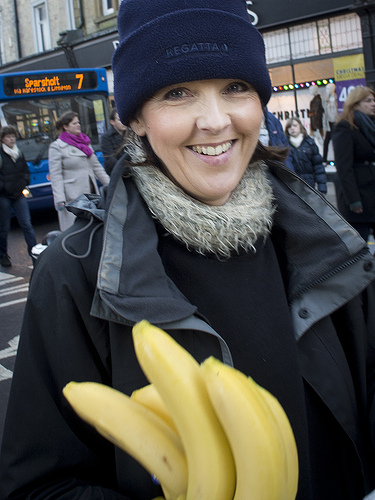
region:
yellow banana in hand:
[203, 361, 283, 497]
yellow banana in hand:
[75, 393, 178, 486]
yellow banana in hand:
[141, 329, 203, 497]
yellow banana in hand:
[132, 388, 156, 413]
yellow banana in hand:
[240, 386, 295, 452]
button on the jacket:
[291, 308, 313, 324]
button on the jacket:
[360, 261, 373, 274]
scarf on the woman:
[180, 213, 250, 248]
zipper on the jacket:
[323, 271, 347, 279]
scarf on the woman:
[70, 134, 92, 157]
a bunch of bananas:
[60, 319, 303, 499]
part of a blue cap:
[83, 0, 282, 124]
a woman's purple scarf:
[56, 128, 94, 159]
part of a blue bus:
[0, 66, 108, 204]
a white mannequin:
[301, 85, 327, 154]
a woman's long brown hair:
[338, 85, 373, 125]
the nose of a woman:
[193, 90, 232, 137]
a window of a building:
[32, 6, 49, 52]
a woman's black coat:
[286, 137, 329, 192]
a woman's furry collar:
[125, 145, 273, 252]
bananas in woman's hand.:
[186, 424, 224, 471]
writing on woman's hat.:
[167, 42, 236, 54]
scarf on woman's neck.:
[70, 137, 95, 154]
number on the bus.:
[73, 71, 89, 92]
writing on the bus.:
[11, 74, 71, 98]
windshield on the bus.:
[24, 111, 48, 130]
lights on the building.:
[280, 81, 306, 94]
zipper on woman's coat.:
[303, 247, 359, 294]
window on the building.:
[39, 6, 45, 53]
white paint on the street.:
[7, 277, 23, 293]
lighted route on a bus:
[4, 58, 114, 99]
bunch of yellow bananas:
[45, 309, 346, 497]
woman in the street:
[13, 3, 363, 498]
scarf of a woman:
[131, 171, 297, 260]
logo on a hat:
[161, 35, 234, 65]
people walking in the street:
[0, 118, 118, 276]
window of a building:
[27, 2, 56, 61]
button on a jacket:
[289, 305, 317, 322]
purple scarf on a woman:
[60, 131, 100, 161]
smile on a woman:
[180, 134, 258, 170]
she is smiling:
[177, 132, 240, 163]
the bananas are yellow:
[179, 413, 230, 441]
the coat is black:
[42, 302, 85, 351]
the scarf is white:
[168, 195, 201, 236]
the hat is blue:
[116, 4, 178, 49]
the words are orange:
[15, 79, 68, 92]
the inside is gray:
[293, 197, 331, 245]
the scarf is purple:
[66, 131, 90, 152]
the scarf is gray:
[352, 112, 370, 130]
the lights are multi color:
[278, 81, 308, 90]